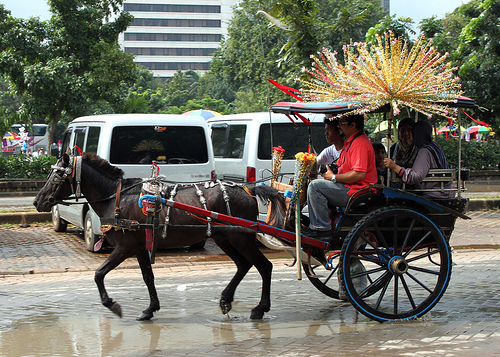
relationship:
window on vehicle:
[111, 123, 211, 170] [46, 106, 224, 253]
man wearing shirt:
[305, 111, 375, 240] [330, 136, 377, 193]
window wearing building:
[122, 4, 225, 78] [95, 0, 242, 85]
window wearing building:
[126, 12, 225, 29] [95, 0, 242, 85]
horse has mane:
[32, 148, 274, 318] [83, 147, 138, 184]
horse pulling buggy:
[32, 144, 287, 322] [270, 52, 481, 325]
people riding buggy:
[295, 110, 455, 239] [256, 88, 473, 325]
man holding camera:
[306, 109, 376, 234] [301, 149, 351, 196]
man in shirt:
[305, 111, 375, 240] [341, 138, 370, 171]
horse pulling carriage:
[32, 148, 274, 318] [32, 29, 477, 323]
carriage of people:
[32, 29, 477, 323] [291, 110, 456, 237]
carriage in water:
[132, 29, 478, 332] [4, 255, 498, 344]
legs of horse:
[89, 242, 309, 333] [66, 148, 288, 320]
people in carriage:
[285, 110, 461, 227] [256, 92, 465, 320]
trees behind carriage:
[4, 0, 286, 109] [214, 29, 480, 324]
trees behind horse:
[4, 0, 286, 109] [32, 148, 274, 318]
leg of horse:
[93, 234, 138, 314] [32, 148, 274, 318]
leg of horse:
[90, 245, 130, 318] [32, 148, 274, 318]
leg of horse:
[235, 233, 273, 320] [32, 148, 274, 318]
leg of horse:
[209, 232, 253, 313] [32, 148, 274, 318]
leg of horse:
[249, 242, 272, 329] [32, 148, 274, 318]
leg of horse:
[223, 231, 273, 319] [32, 148, 274, 318]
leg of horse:
[135, 231, 162, 321] [32, 148, 274, 318]